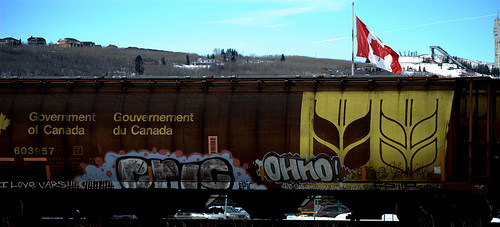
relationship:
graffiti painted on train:
[254, 151, 349, 185] [0, 75, 499, 227]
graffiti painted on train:
[71, 147, 268, 191] [0, 75, 499, 227]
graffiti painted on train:
[0, 180, 114, 189] [0, 75, 499, 227]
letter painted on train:
[113, 112, 122, 123] [0, 75, 499, 227]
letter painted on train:
[130, 125, 139, 136] [0, 75, 499, 227]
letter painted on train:
[91, 112, 97, 123] [0, 75, 499, 227]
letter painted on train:
[166, 127, 174, 136] [0, 75, 499, 227]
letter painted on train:
[27, 126, 35, 135] [0, 75, 499, 227]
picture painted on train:
[299, 89, 455, 190] [0, 75, 499, 227]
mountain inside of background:
[0, 44, 499, 78] [1, 1, 500, 223]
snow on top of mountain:
[398, 53, 499, 78] [0, 44, 499, 78]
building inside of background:
[1, 37, 22, 48] [1, 1, 500, 223]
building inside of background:
[27, 36, 47, 45] [1, 1, 500, 223]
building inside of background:
[56, 37, 96, 48] [1, 1, 500, 223]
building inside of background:
[191, 57, 216, 66] [1, 1, 500, 223]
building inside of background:
[492, 18, 500, 69] [1, 1, 500, 223]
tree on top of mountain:
[133, 54, 145, 75] [0, 44, 499, 78]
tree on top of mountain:
[185, 54, 191, 66] [0, 44, 499, 78]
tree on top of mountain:
[280, 53, 286, 61] [0, 44, 499, 78]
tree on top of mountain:
[161, 56, 167, 65] [0, 44, 499, 78]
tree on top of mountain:
[231, 53, 237, 62] [0, 44, 499, 78]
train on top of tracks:
[0, 75, 499, 227] [42, 218, 500, 226]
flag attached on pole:
[355, 16, 402, 75] [350, 1, 354, 76]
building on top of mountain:
[1, 37, 22, 48] [0, 44, 499, 78]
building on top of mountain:
[27, 36, 47, 45] [0, 44, 499, 78]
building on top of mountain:
[492, 18, 500, 69] [0, 44, 499, 78]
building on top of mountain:
[191, 57, 216, 66] [0, 44, 499, 78]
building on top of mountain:
[56, 37, 96, 48] [0, 44, 499, 78]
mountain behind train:
[0, 44, 499, 78] [0, 75, 499, 227]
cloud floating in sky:
[224, 0, 340, 27] [1, 0, 500, 63]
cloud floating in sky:
[310, 0, 342, 15] [1, 0, 500, 63]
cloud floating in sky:
[312, 13, 500, 44] [1, 0, 500, 63]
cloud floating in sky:
[142, 36, 365, 63] [1, 0, 500, 63]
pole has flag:
[350, 1, 354, 76] [355, 16, 402, 75]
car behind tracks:
[314, 204, 353, 218] [42, 218, 500, 226]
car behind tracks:
[210, 205, 247, 220] [42, 218, 500, 226]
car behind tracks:
[192, 212, 227, 220] [42, 218, 500, 226]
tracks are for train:
[42, 218, 500, 226] [0, 75, 499, 227]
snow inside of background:
[398, 53, 499, 78] [1, 1, 500, 223]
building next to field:
[1, 37, 22, 48] [0, 44, 393, 78]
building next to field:
[27, 36, 47, 45] [0, 44, 393, 78]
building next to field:
[56, 37, 96, 48] [0, 44, 393, 78]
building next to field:
[191, 57, 216, 66] [0, 44, 393, 78]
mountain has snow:
[0, 44, 499, 78] [398, 53, 499, 78]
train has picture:
[0, 75, 499, 227] [299, 89, 455, 190]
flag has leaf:
[355, 16, 402, 75] [369, 38, 392, 61]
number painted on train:
[48, 146, 55, 155] [0, 75, 499, 227]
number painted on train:
[41, 146, 48, 156] [0, 75, 499, 227]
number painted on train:
[27, 146, 34, 155] [0, 75, 499, 227]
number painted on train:
[20, 147, 26, 155] [0, 75, 499, 227]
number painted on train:
[13, 146, 20, 155] [0, 75, 499, 227]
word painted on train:
[27, 125, 40, 136] [0, 75, 499, 227]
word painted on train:
[43, 124, 85, 136] [0, 75, 499, 227]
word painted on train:
[111, 126, 127, 136] [0, 75, 499, 227]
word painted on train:
[131, 124, 174, 136] [0, 75, 499, 227]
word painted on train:
[113, 111, 195, 123] [0, 75, 499, 227]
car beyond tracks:
[314, 204, 353, 218] [42, 218, 500, 226]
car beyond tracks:
[210, 205, 247, 220] [42, 218, 500, 226]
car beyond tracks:
[192, 212, 227, 220] [42, 218, 500, 226]